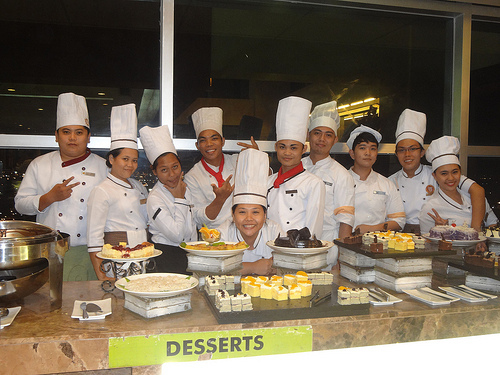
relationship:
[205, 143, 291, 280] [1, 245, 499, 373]
chef leaning on counter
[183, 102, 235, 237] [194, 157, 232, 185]
chefs wearing red scarves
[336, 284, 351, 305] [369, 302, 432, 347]
dessert on table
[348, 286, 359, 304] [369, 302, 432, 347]
dessert on table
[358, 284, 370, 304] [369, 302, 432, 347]
dessert on table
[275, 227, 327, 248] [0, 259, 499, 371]
desserts on table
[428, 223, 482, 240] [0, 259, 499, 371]
desserts on table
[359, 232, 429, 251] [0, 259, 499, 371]
desserts on table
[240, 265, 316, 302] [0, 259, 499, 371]
dessert on table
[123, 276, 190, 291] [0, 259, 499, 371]
desserts on table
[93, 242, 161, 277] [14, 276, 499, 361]
desert on table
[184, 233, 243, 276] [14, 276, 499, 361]
dessert on table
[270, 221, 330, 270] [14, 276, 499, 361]
desert on table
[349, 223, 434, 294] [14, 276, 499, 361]
dessert on table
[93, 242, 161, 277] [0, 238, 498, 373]
desert on table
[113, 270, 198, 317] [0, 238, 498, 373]
desert on table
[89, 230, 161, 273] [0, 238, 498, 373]
desert on table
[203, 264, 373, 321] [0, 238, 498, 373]
desert on table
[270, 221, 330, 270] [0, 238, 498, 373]
desert on table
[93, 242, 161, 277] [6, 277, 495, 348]
desert on table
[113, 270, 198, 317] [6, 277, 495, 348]
desert on table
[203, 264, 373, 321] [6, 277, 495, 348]
desert on table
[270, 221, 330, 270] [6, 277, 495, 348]
desert on table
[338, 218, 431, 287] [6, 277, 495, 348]
desert on table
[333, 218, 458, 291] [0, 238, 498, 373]
desert on table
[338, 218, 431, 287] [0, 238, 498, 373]
desert on table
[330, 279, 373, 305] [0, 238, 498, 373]
dessert on table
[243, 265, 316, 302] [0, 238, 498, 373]
dessert on table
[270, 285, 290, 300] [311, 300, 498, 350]
dessert on marble table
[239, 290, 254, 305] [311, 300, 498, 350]
dessert on marble table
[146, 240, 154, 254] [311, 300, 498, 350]
dessert on marble table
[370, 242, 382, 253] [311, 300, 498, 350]
dessert on marble table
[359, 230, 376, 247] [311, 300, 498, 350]
dessert on marble table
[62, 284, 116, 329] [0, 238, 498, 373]
platter on table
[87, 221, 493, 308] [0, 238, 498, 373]
food on table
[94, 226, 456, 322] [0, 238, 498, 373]
food on table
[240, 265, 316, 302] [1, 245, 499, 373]
dessert on counter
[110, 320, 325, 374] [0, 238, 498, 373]
sign on table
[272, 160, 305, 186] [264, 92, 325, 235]
fabric around chefs